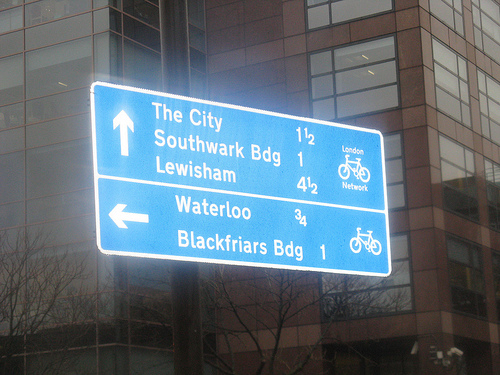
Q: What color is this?
A: Blue.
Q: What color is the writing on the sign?
A: White.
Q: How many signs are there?
A: One.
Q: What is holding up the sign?
A: Poles.